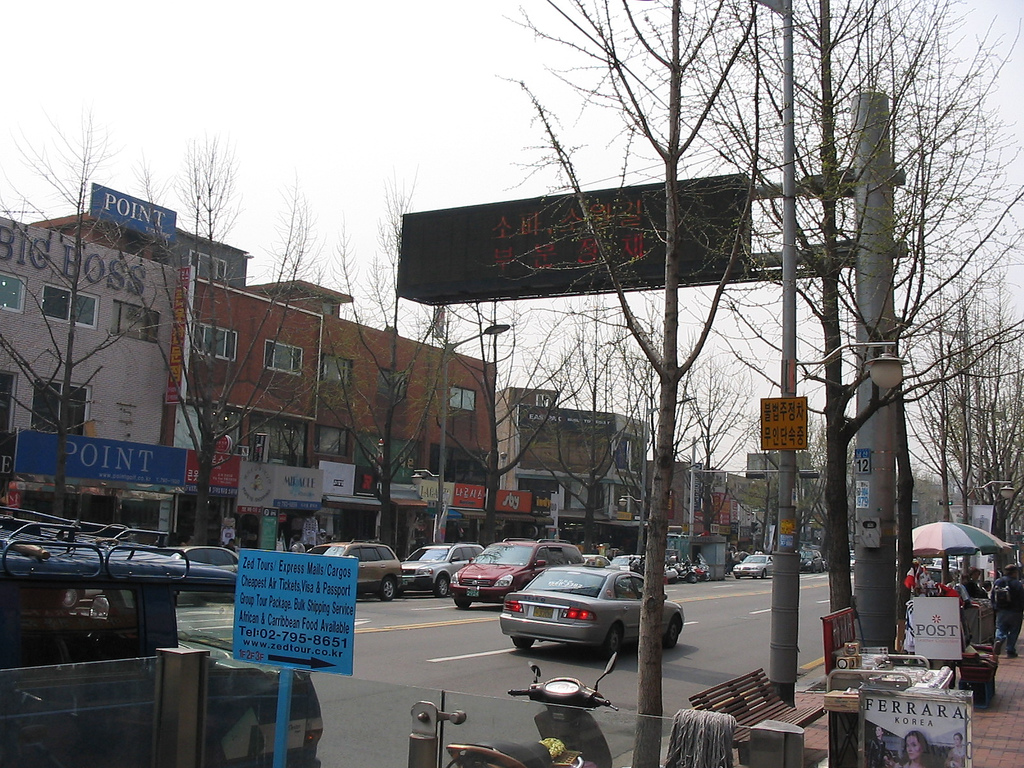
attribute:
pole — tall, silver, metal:
[752, 399, 835, 763]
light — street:
[752, 49, 804, 762]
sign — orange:
[729, 378, 885, 478]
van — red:
[397, 535, 620, 620]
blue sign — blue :
[0, 413, 206, 502]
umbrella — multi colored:
[870, 493, 1020, 571]